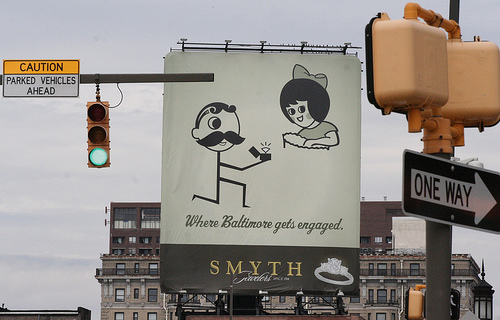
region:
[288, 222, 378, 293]
silver ring on billboard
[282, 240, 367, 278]
silver ring on billboard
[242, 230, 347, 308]
silver ring on billboard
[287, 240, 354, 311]
silver ring on billboard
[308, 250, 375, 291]
silver ring on billboard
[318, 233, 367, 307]
a ring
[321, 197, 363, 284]
a ring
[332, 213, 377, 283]
a ring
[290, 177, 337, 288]
a ring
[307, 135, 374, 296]
a ring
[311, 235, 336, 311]
a ring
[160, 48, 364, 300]
Advertising sign for jewelers.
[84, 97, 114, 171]
Green stop light up above.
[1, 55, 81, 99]
Caution sign up above.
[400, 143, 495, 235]
One way sign pointing right.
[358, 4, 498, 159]
More traffice sign on a pole.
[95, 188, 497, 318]
Buildings inthe background.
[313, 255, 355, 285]
Picture of an engagement ring.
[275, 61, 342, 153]
Cartoon of a girl.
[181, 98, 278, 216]
Picture of a cartoon man kneeling.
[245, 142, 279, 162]
Cartoon picture of a diamond ring in a box.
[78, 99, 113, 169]
traffic light on green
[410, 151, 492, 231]
one way sign on pole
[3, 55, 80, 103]
a sign on pole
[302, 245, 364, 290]
picture of a ring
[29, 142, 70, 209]
part of the sky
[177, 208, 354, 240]
wording on the post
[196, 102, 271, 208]
cartoon man holding ring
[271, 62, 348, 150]
female cartoon character on poster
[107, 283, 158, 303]
windows in the building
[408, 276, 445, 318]
yellow object on pole